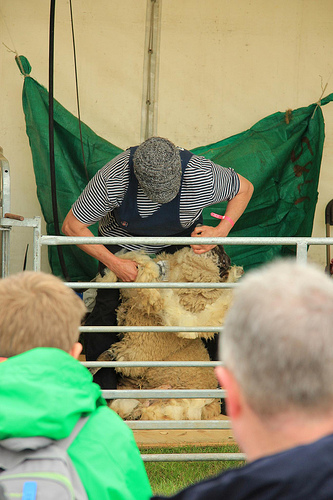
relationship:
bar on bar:
[34, 234, 333, 461] [34, 234, 333, 461]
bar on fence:
[34, 234, 333, 461] [32, 221, 332, 400]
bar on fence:
[34, 234, 333, 461] [29, 214, 332, 472]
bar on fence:
[34, 234, 333, 461] [10, 203, 322, 456]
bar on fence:
[34, 234, 333, 461] [29, 210, 331, 333]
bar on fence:
[280, 237, 319, 248] [10, 203, 322, 456]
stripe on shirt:
[105, 180, 127, 188] [67, 148, 246, 253]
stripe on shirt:
[108, 190, 127, 197] [67, 148, 246, 253]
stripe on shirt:
[107, 195, 123, 200] [67, 148, 246, 253]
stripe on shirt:
[105, 196, 122, 201] [67, 148, 246, 253]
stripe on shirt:
[109, 197, 123, 202] [67, 148, 246, 253]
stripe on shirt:
[105, 219, 119, 232] [67, 148, 246, 253]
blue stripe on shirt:
[139, 203, 155, 209] [70, 147, 240, 256]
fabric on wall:
[16, 55, 331, 341] [0, 0, 332, 319]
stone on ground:
[159, 428, 170, 433] [0, 360, 330, 498]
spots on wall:
[210, 28, 261, 55] [0, 1, 330, 412]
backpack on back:
[5, 433, 87, 496] [0, 404, 87, 498]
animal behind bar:
[87, 244, 242, 439] [34, 234, 333, 461]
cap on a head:
[133, 137, 182, 204] [132, 136, 182, 203]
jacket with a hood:
[1, 343, 155, 498] [0, 346, 101, 437]